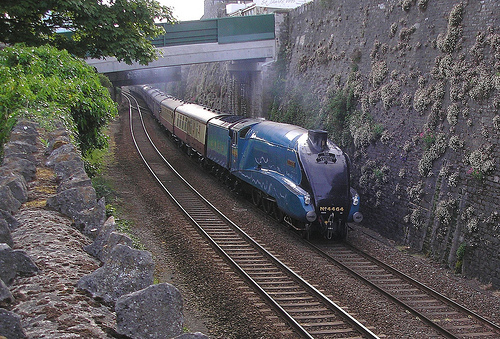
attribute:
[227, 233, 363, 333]
tracks — train, set 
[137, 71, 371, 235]
train — Long 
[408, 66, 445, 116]
moss — growing 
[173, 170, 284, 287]
tracks — side 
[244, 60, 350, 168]
steam — rising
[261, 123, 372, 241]
engine — train 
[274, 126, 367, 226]
engine — train 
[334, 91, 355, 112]
engine — blue train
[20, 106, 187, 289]
side — cliff  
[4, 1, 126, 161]
bushes — large 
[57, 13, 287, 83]
tunnel — brick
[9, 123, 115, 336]
path — brick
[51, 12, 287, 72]
tunneled path — covered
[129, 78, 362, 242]
passenger train — long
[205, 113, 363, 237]
train engine — blue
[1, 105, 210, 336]
stone wall — tall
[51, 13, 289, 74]
tunnel — modern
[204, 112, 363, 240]
engine — blue